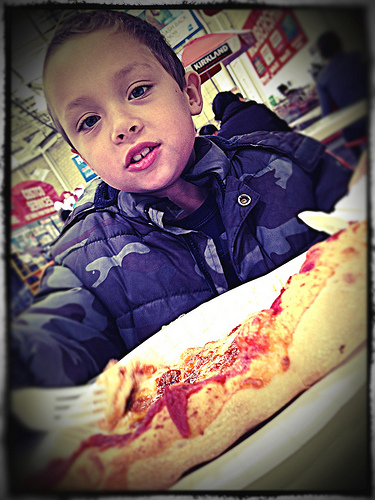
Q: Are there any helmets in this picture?
A: No, there are no helmets.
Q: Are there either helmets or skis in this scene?
A: No, there are no helmets or skis.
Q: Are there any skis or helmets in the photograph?
A: No, there are no helmets or skis.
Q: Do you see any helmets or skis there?
A: No, there are no helmets or skis.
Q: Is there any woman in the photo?
A: No, there are no women.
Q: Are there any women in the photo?
A: No, there are no women.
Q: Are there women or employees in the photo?
A: No, there are no women or employees.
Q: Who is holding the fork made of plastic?
A: The boy is holding the fork.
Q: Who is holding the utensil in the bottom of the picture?
A: The boy is holding the fork.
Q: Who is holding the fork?
A: The boy is holding the fork.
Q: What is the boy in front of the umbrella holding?
A: The boy is holding the fork.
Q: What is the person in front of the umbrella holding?
A: The boy is holding the fork.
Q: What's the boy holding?
A: The boy is holding the fork.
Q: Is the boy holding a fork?
A: Yes, the boy is holding a fork.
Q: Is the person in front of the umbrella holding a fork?
A: Yes, the boy is holding a fork.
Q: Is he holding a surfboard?
A: No, the boy is holding a fork.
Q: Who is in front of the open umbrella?
A: The boy is in front of the umbrella.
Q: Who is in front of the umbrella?
A: The boy is in front of the umbrella.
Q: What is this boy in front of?
A: The boy is in front of the umbrella.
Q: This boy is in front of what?
A: The boy is in front of the umbrella.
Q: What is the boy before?
A: The boy is in front of the umbrella.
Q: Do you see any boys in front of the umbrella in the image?
A: Yes, there is a boy in front of the umbrella.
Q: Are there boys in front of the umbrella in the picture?
A: Yes, there is a boy in front of the umbrella.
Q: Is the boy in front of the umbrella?
A: Yes, the boy is in front of the umbrella.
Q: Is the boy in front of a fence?
A: No, the boy is in front of the umbrella.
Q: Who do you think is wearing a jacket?
A: The boy is wearing a jacket.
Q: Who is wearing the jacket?
A: The boy is wearing a jacket.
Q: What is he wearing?
A: The boy is wearing a jacket.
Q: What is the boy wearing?
A: The boy is wearing a jacket.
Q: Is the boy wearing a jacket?
A: Yes, the boy is wearing a jacket.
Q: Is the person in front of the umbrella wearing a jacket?
A: Yes, the boy is wearing a jacket.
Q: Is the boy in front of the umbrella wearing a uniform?
A: No, the boy is wearing a jacket.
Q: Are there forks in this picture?
A: Yes, there is a fork.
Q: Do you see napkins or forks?
A: Yes, there is a fork.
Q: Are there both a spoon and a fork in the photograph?
A: No, there is a fork but no spoons.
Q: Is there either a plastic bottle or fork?
A: Yes, there is a plastic fork.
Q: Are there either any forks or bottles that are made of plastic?
A: Yes, the fork is made of plastic.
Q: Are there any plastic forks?
A: Yes, there is a fork that is made of plastic.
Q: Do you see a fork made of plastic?
A: Yes, there is a fork that is made of plastic.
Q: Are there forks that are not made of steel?
A: Yes, there is a fork that is made of plastic.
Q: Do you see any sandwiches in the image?
A: No, there are no sandwiches.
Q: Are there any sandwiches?
A: No, there are no sandwiches.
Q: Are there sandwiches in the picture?
A: No, there are no sandwiches.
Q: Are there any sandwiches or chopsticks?
A: No, there are no sandwiches or chopsticks.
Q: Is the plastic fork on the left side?
A: Yes, the fork is on the left of the image.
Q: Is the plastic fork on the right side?
A: No, the fork is on the left of the image.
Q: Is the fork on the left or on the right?
A: The fork is on the left of the image.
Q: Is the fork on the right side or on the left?
A: The fork is on the left of the image.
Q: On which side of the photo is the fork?
A: The fork is on the left of the image.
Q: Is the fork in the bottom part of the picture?
A: Yes, the fork is in the bottom of the image.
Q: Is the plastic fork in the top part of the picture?
A: No, the fork is in the bottom of the image.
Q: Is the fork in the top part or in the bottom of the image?
A: The fork is in the bottom of the image.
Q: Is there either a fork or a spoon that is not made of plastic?
A: No, there is a fork but it is made of plastic.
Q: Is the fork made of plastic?
A: Yes, the fork is made of plastic.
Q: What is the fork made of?
A: The fork is made of plastic.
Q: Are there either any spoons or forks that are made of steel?
A: No, there is a fork but it is made of plastic.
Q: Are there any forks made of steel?
A: No, there is a fork but it is made of plastic.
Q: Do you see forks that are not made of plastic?
A: No, there is a fork but it is made of plastic.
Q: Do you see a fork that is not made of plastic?
A: No, there is a fork but it is made of plastic.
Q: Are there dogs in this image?
A: No, there are no dogs.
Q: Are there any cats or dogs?
A: No, there are no dogs or cats.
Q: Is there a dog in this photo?
A: No, there are no dogs.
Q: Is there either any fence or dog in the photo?
A: No, there are no dogs or fences.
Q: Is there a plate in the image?
A: Yes, there is a plate.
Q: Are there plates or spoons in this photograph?
A: Yes, there is a plate.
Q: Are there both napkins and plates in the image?
A: No, there is a plate but no napkins.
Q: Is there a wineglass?
A: No, there are no wine glasses.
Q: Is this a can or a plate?
A: This is a plate.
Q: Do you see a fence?
A: No, there are no fences.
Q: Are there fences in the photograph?
A: No, there are no fences.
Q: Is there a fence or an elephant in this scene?
A: No, there are no fences or elephants.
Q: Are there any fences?
A: No, there are no fences.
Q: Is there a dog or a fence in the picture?
A: No, there are no fences or dogs.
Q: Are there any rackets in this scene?
A: No, there are no rackets.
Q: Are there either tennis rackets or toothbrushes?
A: No, there are no tennis rackets or toothbrushes.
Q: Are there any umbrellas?
A: Yes, there is an umbrella.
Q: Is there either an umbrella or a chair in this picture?
A: Yes, there is an umbrella.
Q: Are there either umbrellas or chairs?
A: Yes, there is an umbrella.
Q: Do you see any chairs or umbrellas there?
A: Yes, there is an umbrella.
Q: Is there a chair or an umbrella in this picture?
A: Yes, there is an umbrella.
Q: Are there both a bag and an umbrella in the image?
A: No, there is an umbrella but no bags.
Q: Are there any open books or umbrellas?
A: Yes, there is an open umbrella.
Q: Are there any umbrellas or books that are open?
A: Yes, the umbrella is open.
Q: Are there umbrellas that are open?
A: Yes, there is an open umbrella.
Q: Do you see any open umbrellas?
A: Yes, there is an open umbrella.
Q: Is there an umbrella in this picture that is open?
A: Yes, there is an umbrella that is open.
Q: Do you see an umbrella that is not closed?
A: Yes, there is a open umbrella.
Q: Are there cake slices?
A: No, there are no cake slices.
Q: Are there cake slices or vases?
A: No, there are no cake slices or vases.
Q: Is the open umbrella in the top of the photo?
A: Yes, the umbrella is in the top of the image.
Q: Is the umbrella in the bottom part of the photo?
A: No, the umbrella is in the top of the image.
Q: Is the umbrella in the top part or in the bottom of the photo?
A: The umbrella is in the top of the image.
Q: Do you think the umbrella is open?
A: Yes, the umbrella is open.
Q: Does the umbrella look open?
A: Yes, the umbrella is open.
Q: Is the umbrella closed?
A: No, the umbrella is open.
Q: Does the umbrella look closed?
A: No, the umbrella is open.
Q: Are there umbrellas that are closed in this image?
A: No, there is an umbrella but it is open.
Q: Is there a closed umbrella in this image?
A: No, there is an umbrella but it is open.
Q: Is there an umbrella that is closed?
A: No, there is an umbrella but it is open.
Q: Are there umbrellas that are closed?
A: No, there is an umbrella but it is open.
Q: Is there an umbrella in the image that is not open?
A: No, there is an umbrella but it is open.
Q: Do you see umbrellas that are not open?
A: No, there is an umbrella but it is open.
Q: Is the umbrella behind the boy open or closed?
A: The umbrella is open.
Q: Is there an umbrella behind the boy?
A: Yes, there is an umbrella behind the boy.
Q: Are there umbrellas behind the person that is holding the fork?
A: Yes, there is an umbrella behind the boy.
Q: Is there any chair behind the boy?
A: No, there is an umbrella behind the boy.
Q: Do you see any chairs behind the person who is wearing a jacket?
A: No, there is an umbrella behind the boy.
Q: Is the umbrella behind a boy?
A: Yes, the umbrella is behind a boy.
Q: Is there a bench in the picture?
A: No, there are no benches.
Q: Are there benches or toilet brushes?
A: No, there are no benches or toilet brushes.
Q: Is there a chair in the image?
A: No, there are no chairs.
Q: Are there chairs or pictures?
A: No, there are no chairs or pictures.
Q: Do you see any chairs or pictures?
A: No, there are no chairs or pictures.